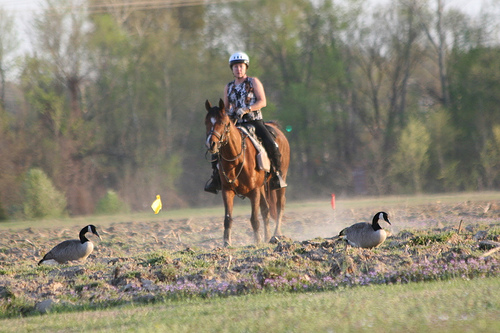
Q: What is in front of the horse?
A: Two ducks.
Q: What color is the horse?
A: Brown.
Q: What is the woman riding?
A: A horse.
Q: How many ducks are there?
A: Two.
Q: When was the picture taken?
A: Day time.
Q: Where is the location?
A: A field.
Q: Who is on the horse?
A: A woman.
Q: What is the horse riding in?
A: A field.